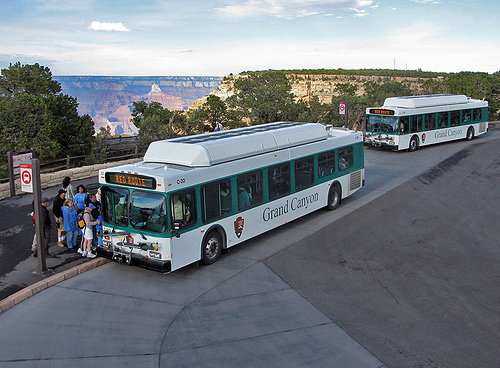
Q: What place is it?
A: It is a street.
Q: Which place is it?
A: It is a street.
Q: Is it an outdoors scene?
A: Yes, it is outdoors.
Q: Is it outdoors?
A: Yes, it is outdoors.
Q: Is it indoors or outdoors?
A: It is outdoors.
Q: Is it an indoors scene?
A: No, it is outdoors.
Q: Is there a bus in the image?
A: Yes, there is a bus.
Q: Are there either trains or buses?
A: Yes, there is a bus.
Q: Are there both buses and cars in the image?
A: No, there is a bus but no cars.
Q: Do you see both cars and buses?
A: No, there is a bus but no cars.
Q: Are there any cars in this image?
A: No, there are no cars.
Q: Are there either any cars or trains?
A: No, there are no cars or trains.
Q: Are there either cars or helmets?
A: No, there are no cars or helmets.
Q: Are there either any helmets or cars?
A: No, there are no cars or helmets.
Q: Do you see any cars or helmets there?
A: No, there are no cars or helmets.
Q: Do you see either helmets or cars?
A: No, there are no cars or helmets.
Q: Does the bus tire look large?
A: Yes, the tire is large.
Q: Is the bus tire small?
A: No, the tire is large.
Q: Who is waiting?
A: The people are waiting.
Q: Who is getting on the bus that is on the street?
A: The people are getting on the bus.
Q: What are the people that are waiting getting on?
A: The people are getting on the bus.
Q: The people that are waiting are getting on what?
A: The people are getting on the bus.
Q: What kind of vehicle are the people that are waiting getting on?
A: The people are getting on the bus.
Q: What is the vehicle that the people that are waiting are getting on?
A: The vehicle is a bus.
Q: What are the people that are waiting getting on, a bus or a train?
A: The people are getting on a bus.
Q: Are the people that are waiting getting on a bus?
A: Yes, the people are getting on a bus.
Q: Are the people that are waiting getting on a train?
A: No, the people are getting on a bus.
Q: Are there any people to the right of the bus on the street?
A: No, the people are to the left of the bus.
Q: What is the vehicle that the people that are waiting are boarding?
A: The vehicle is a bus.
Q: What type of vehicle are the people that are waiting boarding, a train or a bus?
A: The people are boarding a bus.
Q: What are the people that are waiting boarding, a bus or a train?
A: The people are boarding a bus.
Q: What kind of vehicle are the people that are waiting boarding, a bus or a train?
A: The people are boarding a bus.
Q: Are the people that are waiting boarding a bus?
A: Yes, the people are boarding a bus.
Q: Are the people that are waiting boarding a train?
A: No, the people are boarding a bus.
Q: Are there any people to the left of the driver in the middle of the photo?
A: Yes, there are people to the left of the driver.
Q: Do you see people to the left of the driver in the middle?
A: Yes, there are people to the left of the driver.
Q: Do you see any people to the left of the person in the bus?
A: Yes, there are people to the left of the driver.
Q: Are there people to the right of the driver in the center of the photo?
A: No, the people are to the left of the driver.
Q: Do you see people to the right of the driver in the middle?
A: No, the people are to the left of the driver.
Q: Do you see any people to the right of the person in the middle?
A: No, the people are to the left of the driver.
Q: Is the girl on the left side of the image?
A: Yes, the girl is on the left of the image.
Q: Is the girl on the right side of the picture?
A: No, the girl is on the left of the image.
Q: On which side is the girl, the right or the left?
A: The girl is on the left of the image.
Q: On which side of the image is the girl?
A: The girl is on the left of the image.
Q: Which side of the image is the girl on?
A: The girl is on the left of the image.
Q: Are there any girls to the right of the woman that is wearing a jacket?
A: Yes, there is a girl to the right of the woman.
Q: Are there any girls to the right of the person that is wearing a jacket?
A: Yes, there is a girl to the right of the woman.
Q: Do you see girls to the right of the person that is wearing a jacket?
A: Yes, there is a girl to the right of the woman.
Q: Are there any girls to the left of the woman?
A: No, the girl is to the right of the woman.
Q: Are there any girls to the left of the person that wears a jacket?
A: No, the girl is to the right of the woman.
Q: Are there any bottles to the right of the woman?
A: No, there is a girl to the right of the woman.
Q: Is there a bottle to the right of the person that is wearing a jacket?
A: No, there is a girl to the right of the woman.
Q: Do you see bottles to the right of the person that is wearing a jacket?
A: No, there is a girl to the right of the woman.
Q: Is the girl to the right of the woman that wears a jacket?
A: Yes, the girl is to the right of the woman.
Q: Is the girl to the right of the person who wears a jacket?
A: Yes, the girl is to the right of the woman.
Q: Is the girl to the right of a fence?
A: No, the girl is to the right of the woman.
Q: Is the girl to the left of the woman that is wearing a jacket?
A: No, the girl is to the right of the woman.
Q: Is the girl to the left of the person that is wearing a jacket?
A: No, the girl is to the right of the woman.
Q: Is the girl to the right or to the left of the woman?
A: The girl is to the right of the woman.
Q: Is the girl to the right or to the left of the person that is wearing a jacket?
A: The girl is to the right of the woman.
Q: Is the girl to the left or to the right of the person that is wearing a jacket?
A: The girl is to the right of the woman.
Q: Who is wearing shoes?
A: The girl is wearing shoes.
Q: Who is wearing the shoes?
A: The girl is wearing shoes.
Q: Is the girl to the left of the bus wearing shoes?
A: Yes, the girl is wearing shoes.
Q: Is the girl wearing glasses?
A: No, the girl is wearing shoes.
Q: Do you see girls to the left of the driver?
A: Yes, there is a girl to the left of the driver.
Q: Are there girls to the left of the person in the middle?
A: Yes, there is a girl to the left of the driver.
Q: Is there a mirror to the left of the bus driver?
A: No, there is a girl to the left of the driver.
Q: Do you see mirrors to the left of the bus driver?
A: No, there is a girl to the left of the driver.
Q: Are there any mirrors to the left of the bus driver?
A: No, there is a girl to the left of the driver.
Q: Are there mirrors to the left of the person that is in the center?
A: No, there is a girl to the left of the driver.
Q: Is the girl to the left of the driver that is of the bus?
A: Yes, the girl is to the left of the driver.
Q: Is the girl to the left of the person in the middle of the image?
A: Yes, the girl is to the left of the driver.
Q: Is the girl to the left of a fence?
A: No, the girl is to the left of the driver.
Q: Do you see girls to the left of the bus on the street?
A: Yes, there is a girl to the left of the bus.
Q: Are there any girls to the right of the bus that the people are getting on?
A: No, the girl is to the left of the bus.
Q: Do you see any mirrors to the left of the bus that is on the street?
A: No, there is a girl to the left of the bus.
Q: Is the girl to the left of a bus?
A: Yes, the girl is to the left of a bus.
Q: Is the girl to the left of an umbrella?
A: No, the girl is to the left of a bus.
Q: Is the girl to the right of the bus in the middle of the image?
A: No, the girl is to the left of the bus.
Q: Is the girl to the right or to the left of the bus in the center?
A: The girl is to the left of the bus.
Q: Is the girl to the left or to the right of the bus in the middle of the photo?
A: The girl is to the left of the bus.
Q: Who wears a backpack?
A: The girl wears a backpack.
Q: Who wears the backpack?
A: The girl wears a backpack.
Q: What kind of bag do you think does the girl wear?
A: The girl wears a backpack.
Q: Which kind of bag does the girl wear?
A: The girl wears a backpack.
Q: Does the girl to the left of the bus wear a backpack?
A: Yes, the girl wears a backpack.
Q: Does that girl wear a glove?
A: No, the girl wears a backpack.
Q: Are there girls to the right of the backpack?
A: Yes, there is a girl to the right of the backpack.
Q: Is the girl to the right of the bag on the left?
A: Yes, the girl is to the right of the backpack.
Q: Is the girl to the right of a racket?
A: No, the girl is to the right of the backpack.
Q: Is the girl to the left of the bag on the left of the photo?
A: No, the girl is to the right of the backpack.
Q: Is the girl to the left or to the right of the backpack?
A: The girl is to the right of the backpack.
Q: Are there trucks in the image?
A: No, there are no trucks.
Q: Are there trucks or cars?
A: No, there are no trucks or cars.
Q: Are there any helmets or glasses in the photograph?
A: No, there are no glasses or helmets.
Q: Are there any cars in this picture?
A: No, there are no cars.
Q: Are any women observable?
A: Yes, there is a woman.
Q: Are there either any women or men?
A: Yes, there is a woman.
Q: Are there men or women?
A: Yes, there is a woman.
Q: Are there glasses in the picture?
A: No, there are no glasses.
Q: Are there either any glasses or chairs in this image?
A: No, there are no glasses or chairs.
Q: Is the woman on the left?
A: Yes, the woman is on the left of the image.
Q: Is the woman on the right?
A: No, the woman is on the left of the image.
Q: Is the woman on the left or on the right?
A: The woman is on the left of the image.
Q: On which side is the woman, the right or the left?
A: The woman is on the left of the image.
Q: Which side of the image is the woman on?
A: The woman is on the left of the image.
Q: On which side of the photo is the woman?
A: The woman is on the left of the image.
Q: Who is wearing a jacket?
A: The woman is wearing a jacket.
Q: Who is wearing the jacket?
A: The woman is wearing a jacket.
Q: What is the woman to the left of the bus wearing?
A: The woman is wearing a jacket.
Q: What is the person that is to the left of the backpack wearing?
A: The woman is wearing a jacket.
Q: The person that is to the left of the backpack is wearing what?
A: The woman is wearing a jacket.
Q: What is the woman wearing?
A: The woman is wearing a jacket.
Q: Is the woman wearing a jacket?
A: Yes, the woman is wearing a jacket.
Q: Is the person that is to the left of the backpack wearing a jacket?
A: Yes, the woman is wearing a jacket.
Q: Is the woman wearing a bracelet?
A: No, the woman is wearing a jacket.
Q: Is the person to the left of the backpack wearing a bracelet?
A: No, the woman is wearing a jacket.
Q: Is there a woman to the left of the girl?
A: Yes, there is a woman to the left of the girl.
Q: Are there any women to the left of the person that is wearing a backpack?
A: Yes, there is a woman to the left of the girl.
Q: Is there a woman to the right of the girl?
A: No, the woman is to the left of the girl.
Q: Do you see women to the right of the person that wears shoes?
A: No, the woman is to the left of the girl.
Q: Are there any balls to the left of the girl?
A: No, there is a woman to the left of the girl.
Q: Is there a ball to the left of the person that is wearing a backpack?
A: No, there is a woman to the left of the girl.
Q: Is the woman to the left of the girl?
A: Yes, the woman is to the left of the girl.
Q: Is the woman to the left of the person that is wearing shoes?
A: Yes, the woman is to the left of the girl.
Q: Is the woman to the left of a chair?
A: No, the woman is to the left of the girl.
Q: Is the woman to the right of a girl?
A: No, the woman is to the left of a girl.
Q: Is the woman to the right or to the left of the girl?
A: The woman is to the left of the girl.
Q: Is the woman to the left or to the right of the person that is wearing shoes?
A: The woman is to the left of the girl.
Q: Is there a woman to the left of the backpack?
A: Yes, there is a woman to the left of the backpack.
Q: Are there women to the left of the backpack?
A: Yes, there is a woman to the left of the backpack.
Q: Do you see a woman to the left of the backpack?
A: Yes, there is a woman to the left of the backpack.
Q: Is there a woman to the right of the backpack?
A: No, the woman is to the left of the backpack.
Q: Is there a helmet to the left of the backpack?
A: No, there is a woman to the left of the backpack.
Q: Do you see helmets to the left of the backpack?
A: No, there is a woman to the left of the backpack.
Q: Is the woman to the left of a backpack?
A: Yes, the woman is to the left of a backpack.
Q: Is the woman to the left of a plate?
A: No, the woman is to the left of a backpack.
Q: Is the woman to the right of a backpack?
A: No, the woman is to the left of a backpack.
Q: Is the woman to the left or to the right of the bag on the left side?
A: The woman is to the left of the backpack.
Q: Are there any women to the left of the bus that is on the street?
A: Yes, there is a woman to the left of the bus.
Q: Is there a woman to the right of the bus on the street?
A: No, the woman is to the left of the bus.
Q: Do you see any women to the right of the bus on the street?
A: No, the woman is to the left of the bus.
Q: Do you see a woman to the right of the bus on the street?
A: No, the woman is to the left of the bus.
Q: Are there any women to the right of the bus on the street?
A: No, the woman is to the left of the bus.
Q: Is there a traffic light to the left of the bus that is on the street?
A: No, there is a woman to the left of the bus.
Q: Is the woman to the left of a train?
A: No, the woman is to the left of the bus.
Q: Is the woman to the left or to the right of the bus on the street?
A: The woman is to the left of the bus.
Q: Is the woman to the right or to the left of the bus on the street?
A: The woman is to the left of the bus.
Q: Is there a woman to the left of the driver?
A: Yes, there is a woman to the left of the driver.